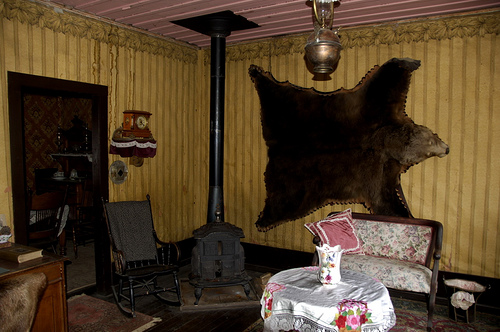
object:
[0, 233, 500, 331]
ground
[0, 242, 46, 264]
book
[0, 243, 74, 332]
counter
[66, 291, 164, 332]
rug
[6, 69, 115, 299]
doorway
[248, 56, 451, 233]
bear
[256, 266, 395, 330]
table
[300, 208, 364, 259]
pillow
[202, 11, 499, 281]
paper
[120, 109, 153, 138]
clock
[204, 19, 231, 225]
pipe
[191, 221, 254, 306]
fireplace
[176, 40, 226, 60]
corner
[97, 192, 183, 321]
rocking chair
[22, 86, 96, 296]
door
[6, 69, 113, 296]
door frame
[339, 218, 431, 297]
fabric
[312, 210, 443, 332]
couch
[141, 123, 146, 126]
clock hand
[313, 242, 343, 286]
vase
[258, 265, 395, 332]
tablecloth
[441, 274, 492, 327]
garbage can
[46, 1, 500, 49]
ceiling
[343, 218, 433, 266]
pattern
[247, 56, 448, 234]
bear skin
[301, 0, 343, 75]
lamp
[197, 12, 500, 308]
wall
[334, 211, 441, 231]
trim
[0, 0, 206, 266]
wallpaper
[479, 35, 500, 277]
stripes